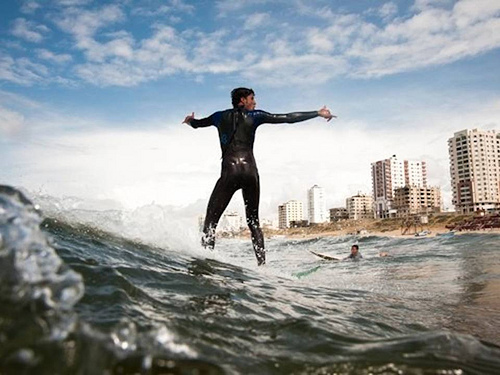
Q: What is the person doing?
A: Surfing.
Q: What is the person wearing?
A: Wetsuit.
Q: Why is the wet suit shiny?
A: Wet.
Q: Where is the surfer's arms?
A: Held out.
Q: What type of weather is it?
A: Sunny.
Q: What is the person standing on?
A: Surfboard.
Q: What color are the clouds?
A: White.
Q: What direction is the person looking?
A: Right.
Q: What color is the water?
A: Grey.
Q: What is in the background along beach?
A: Buildings.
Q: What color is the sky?
A: Blue.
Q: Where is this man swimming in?
A: The beach.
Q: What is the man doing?
A: Surfboarding.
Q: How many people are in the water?
A: 2.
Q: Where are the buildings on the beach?
A: On the right side of the picture.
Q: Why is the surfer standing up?
A: He's catching a wave.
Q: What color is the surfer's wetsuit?
A: Black.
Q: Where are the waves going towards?
A: The sandy beach.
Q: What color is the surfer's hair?
A: Black.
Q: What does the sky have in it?
A: Puffy clouds.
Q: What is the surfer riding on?
A: Water.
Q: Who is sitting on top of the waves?
A: A man surfing.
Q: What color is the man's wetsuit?
A: Black.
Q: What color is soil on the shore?
A: Brown.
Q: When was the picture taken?
A: Daytime.